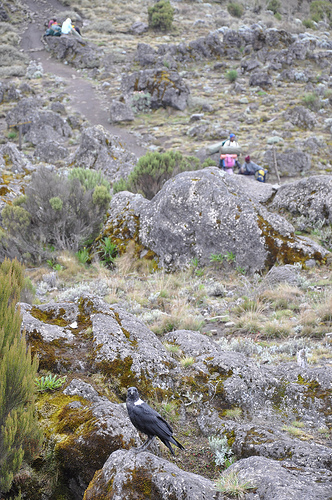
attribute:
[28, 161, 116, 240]
large boulder — grey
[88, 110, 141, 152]
trail — grey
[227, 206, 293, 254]
rocks — grey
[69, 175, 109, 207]
green bushes — dry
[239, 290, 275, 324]
grey bush — dead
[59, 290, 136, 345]
grass — brown